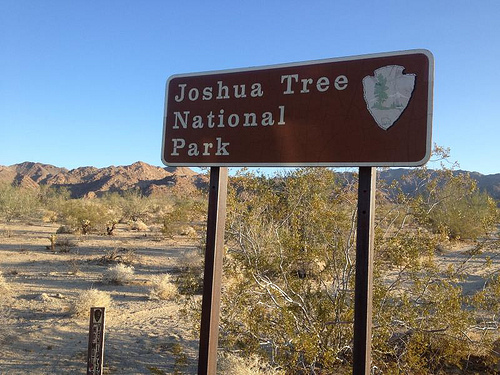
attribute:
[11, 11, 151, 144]
blue sky — clear , blue 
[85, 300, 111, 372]
wooden stake — wooden 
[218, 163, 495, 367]
tree — green 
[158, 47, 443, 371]
metal signpost — metal 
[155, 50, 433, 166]
park sign — rectangular 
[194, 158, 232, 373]
brown stand — brown 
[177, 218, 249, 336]
brown stand — brown 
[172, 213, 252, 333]
brown stand — brown 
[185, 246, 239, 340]
brown stand — brown 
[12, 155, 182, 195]
hills — bare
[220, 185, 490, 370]
bush — dry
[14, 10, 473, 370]
park — joshua tree national park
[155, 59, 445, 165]
sign — red 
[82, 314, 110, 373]
post — mettalic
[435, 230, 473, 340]
land — very dry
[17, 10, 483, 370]
photo —  hot and dry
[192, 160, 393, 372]
metal — brown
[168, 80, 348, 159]
letters — white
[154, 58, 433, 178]
sign —  brown park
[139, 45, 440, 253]
sign —   sign post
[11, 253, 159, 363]
ground — dirt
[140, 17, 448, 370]
sign — tree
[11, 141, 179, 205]
mountain — distance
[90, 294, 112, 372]
thermometer — sign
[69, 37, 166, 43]
sky — clear blue 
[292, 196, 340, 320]
tree — distance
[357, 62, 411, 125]
head — sign, white arrow 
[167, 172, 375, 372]
post — brown 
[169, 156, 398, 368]
post — brown 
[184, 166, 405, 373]
post — brown 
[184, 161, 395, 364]
post — brown 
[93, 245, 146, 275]
plant — stumpy, short, dark